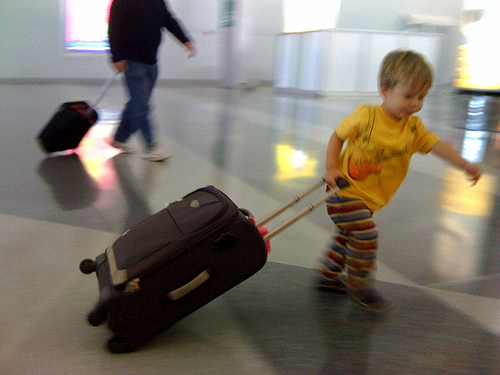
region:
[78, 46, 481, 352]
a child dragging a suitcase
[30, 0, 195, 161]
an adult in jeans pulling a suitcase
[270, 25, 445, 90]
white counters behind the child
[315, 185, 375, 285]
striped pants on the child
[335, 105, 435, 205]
the yellow top the child is wearing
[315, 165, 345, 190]
the handle the child is holding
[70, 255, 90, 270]
a wheel on the child's suitcase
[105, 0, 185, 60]
dark top the adult is wearing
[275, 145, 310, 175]
yellow area with white circle on the floor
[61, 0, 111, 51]
pink tinged window on back wall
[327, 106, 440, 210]
a yellow shirt on a toddler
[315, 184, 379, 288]
striped pants on a toddler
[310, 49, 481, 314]
a toddler pulling a suitcase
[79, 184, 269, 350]
a black suitcase behing pulled by a toddler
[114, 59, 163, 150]
blue jeans on a person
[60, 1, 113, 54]
a window behind a person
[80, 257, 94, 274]
a black wheel on a suitcase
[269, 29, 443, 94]
a white counter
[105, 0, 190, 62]
a black shirt on a person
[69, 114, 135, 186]
the reflection from a window on the floor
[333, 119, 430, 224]
A kid wearing a yellow shirt.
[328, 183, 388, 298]
A kid wearing striped pants.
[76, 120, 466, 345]
A kid dragging a suitcase.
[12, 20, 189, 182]
A person dragging a suitcase.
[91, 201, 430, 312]
A suitcase being dragged by a kid.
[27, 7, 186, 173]
A suitcase being dragged by a person.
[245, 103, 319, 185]
Light refecting off the floor.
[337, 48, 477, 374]
A kid walking on grey floor.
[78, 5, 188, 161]
A person walking on the grey floor.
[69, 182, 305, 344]
Suitcase being dragged on the white floor.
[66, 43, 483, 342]
Little boy trying to pull his weight.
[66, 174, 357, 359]
Black canvas suitcase with handle.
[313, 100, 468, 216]
Yellow tee shirt with red guitar.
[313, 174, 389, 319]
Red, blue, yellow, white striped pants.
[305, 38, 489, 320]
Dirty blonde boy trying to pull his load.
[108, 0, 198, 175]
Person with blue jeans on.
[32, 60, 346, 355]
Two black pull on bags.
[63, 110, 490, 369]
Gray and white granite floors with wax.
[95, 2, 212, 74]
Black pull on shirt for warmth.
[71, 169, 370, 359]
Pull on case has beige handle.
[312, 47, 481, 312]
A small boy pulling a bag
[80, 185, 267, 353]
The blck suitcase the boy is pulling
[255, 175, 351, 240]
Retractable long handle of the suitcase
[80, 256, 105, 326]
Wheels in air of the suitcase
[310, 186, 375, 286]
The striped pants the boy is wearing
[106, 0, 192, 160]
A man walking and pulling a bag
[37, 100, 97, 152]
The bag being pulled by the man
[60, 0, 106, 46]
Window letting in bright sunlight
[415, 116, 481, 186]
Extended left arm of the boy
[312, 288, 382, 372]
Shadow of the boy on the floor